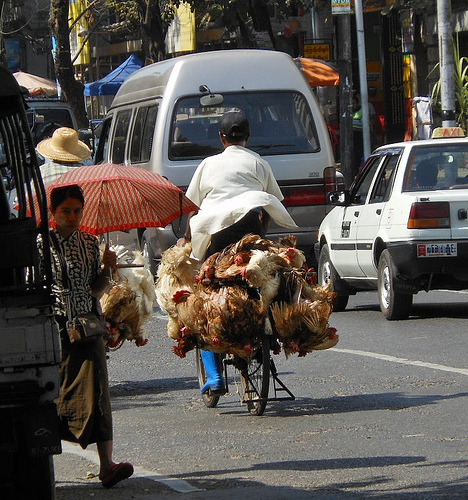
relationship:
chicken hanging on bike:
[222, 293, 265, 362] [196, 325, 294, 416]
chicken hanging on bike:
[279, 246, 306, 269] [196, 325, 294, 416]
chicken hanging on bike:
[272, 272, 328, 350] [196, 325, 294, 416]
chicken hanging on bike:
[171, 338, 195, 359] [196, 325, 294, 416]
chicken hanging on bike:
[194, 252, 215, 286] [196, 325, 294, 416]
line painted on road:
[326, 345, 467, 379] [55, 290, 467, 499]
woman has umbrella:
[36, 185, 132, 487] [14, 162, 201, 281]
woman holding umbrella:
[36, 185, 132, 487] [14, 162, 201, 281]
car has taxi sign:
[313, 137, 468, 320] [431, 126, 465, 139]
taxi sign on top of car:
[431, 126, 465, 139] [313, 137, 468, 320]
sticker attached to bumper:
[417, 242, 460, 258] [388, 241, 467, 277]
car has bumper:
[313, 137, 468, 320] [388, 241, 467, 277]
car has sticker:
[313, 137, 468, 320] [417, 242, 460, 258]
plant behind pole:
[425, 14, 467, 125] [435, 0, 458, 126]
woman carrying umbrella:
[36, 185, 132, 487] [14, 162, 201, 281]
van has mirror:
[94, 49, 337, 262] [200, 84, 225, 107]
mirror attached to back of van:
[200, 84, 225, 107] [94, 49, 337, 262]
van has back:
[94, 49, 337, 262] [153, 49, 336, 269]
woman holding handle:
[36, 185, 132, 487] [102, 183, 114, 282]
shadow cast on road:
[215, 391, 467, 416] [55, 290, 467, 499]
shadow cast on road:
[109, 368, 294, 411] [55, 290, 467, 499]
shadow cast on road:
[344, 302, 467, 320] [55, 290, 467, 499]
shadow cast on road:
[55, 455, 467, 499] [55, 290, 467, 499]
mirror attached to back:
[200, 84, 225, 107] [153, 49, 336, 269]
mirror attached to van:
[200, 84, 225, 107] [94, 49, 337, 262]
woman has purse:
[36, 185, 132, 487] [50, 231, 107, 342]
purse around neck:
[50, 231, 107, 342] [55, 226, 73, 238]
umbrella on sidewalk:
[295, 55, 338, 86] [0, 0, 467, 191]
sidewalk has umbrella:
[0, 0, 467, 191] [295, 55, 338, 86]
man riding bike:
[184, 112, 298, 395] [196, 325, 294, 416]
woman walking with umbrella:
[36, 185, 132, 487] [14, 162, 201, 281]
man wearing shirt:
[184, 112, 298, 395] [187, 145, 298, 259]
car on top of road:
[313, 137, 468, 320] [55, 290, 467, 499]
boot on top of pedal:
[200, 350, 225, 392] [207, 358, 235, 396]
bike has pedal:
[196, 325, 294, 416] [207, 358, 235, 396]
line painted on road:
[62, 440, 214, 495] [55, 290, 467, 499]